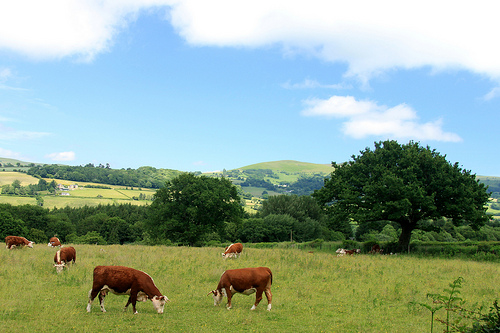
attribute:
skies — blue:
[103, 42, 220, 140]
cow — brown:
[78, 263, 180, 325]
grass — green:
[321, 271, 401, 313]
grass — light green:
[289, 247, 441, 328]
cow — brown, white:
[206, 262, 277, 313]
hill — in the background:
[225, 156, 340, 180]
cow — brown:
[45, 234, 65, 249]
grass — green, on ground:
[0, 233, 498, 331]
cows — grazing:
[211, 268, 276, 310]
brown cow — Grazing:
[4, 228, 35, 253]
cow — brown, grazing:
[190, 266, 292, 313]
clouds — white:
[397, 49, 457, 114]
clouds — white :
[293, 95, 455, 142]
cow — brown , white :
[86, 265, 168, 315]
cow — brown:
[87, 265, 159, 314]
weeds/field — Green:
[398, 274, 483, 322]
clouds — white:
[7, 1, 498, 147]